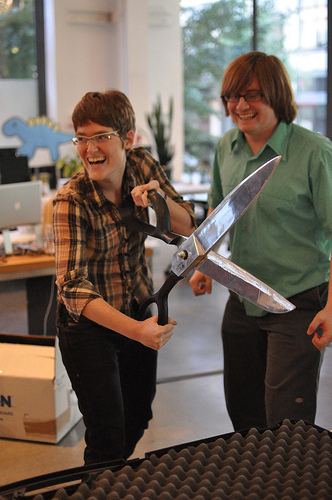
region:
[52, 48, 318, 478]
people in a department store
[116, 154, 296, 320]
giant pair of scissors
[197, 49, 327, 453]
man with pair of scissors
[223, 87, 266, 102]
glasses on the man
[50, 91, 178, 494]
woman with giant scissors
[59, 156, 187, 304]
blouse on the woman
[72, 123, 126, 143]
glasses on the woman's face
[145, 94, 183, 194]
plant in the back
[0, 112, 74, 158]
artwork of dinosaur in back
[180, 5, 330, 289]
window to store front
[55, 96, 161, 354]
this is a lady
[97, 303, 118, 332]
the lady is ight skinned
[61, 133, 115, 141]
this is a spectacle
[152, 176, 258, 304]
this is a scissor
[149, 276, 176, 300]
this is the handle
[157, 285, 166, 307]
the handle is black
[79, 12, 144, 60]
this is the wall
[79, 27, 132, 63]
the wall is white in color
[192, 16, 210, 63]
this is a tree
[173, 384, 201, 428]
this is the floor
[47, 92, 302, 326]
a woman holding a giant pair of scissors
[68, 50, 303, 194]
two people laughing and smiling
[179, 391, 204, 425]
grey surface of the floor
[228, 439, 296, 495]
bumpy grey padding of the case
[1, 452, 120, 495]
the black handle of a case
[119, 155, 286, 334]
grey metal scissors with a black handle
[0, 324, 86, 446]
tan cardboard box on the ground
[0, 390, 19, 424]
blue lettering on the tan cardboard box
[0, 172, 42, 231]
a grey laptop computer on a desk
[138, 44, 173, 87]
white wall of the room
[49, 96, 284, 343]
a woman wolding a giant pair of scissors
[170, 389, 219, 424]
white surface of the floor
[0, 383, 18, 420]
blue lettering on the side of the box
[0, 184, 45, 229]
grey laptop computer on a desk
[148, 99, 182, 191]
a green plant set on a table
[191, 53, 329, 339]
a man wearing a green shirt